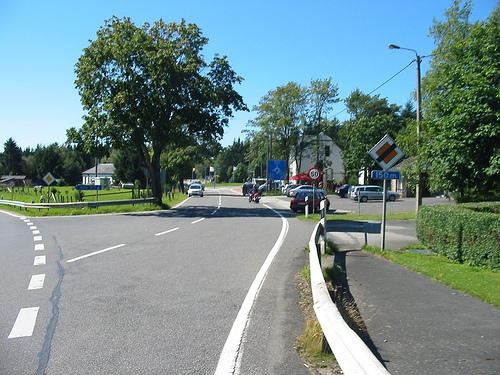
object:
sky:
[0, 2, 500, 154]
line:
[7, 219, 50, 340]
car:
[187, 183, 202, 198]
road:
[0, 206, 285, 373]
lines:
[214, 182, 291, 374]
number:
[307, 167, 321, 181]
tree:
[73, 14, 249, 209]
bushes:
[414, 205, 499, 264]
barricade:
[302, 212, 394, 374]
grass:
[118, 201, 151, 212]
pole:
[311, 182, 315, 214]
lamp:
[336, 188, 341, 193]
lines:
[320, 43, 493, 122]